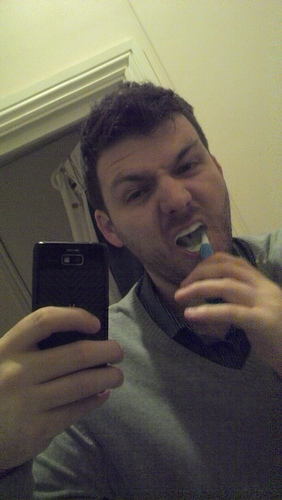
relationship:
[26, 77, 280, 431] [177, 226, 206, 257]
man brushing teeth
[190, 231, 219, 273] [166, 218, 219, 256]
toothbrush in mouth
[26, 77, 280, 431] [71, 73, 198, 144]
man with hair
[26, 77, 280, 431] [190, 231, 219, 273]
man holding toothbrush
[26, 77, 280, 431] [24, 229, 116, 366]
man on phone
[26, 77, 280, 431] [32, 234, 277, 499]
man wearing sweater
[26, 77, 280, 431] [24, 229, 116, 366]
man holding phone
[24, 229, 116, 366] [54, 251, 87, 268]
phone with camera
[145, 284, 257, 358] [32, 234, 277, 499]
shirt under sweater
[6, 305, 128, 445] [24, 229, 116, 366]
hand holding phone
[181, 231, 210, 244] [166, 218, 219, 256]
foam in mouth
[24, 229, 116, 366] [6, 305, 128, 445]
phone in hand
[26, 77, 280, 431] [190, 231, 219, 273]
man using toothbrush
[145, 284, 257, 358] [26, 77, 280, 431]
shirt on man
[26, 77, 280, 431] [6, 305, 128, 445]
man has hand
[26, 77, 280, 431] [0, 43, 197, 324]
man in doorway